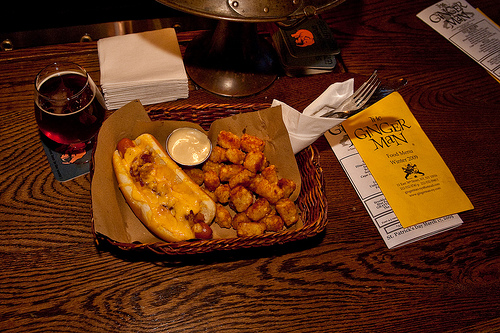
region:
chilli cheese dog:
[91, 125, 218, 244]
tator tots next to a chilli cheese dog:
[101, 126, 298, 236]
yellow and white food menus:
[328, 88, 476, 267]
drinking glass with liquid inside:
[16, 40, 114, 165]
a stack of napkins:
[90, 28, 187, 109]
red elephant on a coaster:
[266, 16, 342, 78]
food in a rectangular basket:
[76, 98, 333, 262]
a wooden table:
[5, 37, 482, 323]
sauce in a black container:
[158, 123, 213, 168]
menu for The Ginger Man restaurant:
[351, 104, 416, 149]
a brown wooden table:
[0, 262, 499, 330]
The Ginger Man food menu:
[415, 0, 499, 80]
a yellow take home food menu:
[341, 88, 475, 246]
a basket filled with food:
[89, 104, 326, 256]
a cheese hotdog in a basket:
[109, 133, 215, 243]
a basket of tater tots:
[210, 127, 298, 238]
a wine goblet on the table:
[31, 58, 106, 168]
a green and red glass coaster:
[41, 138, 93, 182]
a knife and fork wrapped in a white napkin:
[291, 62, 408, 152]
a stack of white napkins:
[96, 26, 189, 108]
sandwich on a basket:
[144, 125, 314, 266]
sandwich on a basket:
[57, 100, 295, 291]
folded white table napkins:
[91, 31, 194, 113]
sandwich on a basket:
[77, 121, 224, 246]